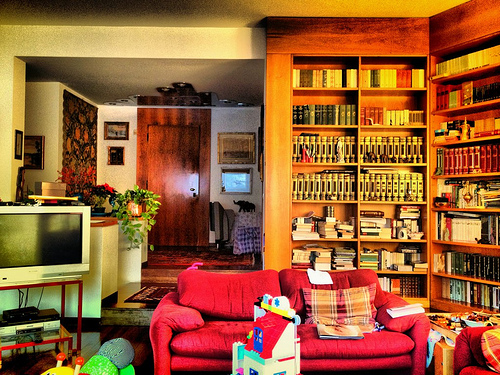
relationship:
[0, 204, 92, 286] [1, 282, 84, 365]
television on stand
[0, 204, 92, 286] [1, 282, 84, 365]
television on top of stand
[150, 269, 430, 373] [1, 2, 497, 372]
sofa in home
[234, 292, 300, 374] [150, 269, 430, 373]
toy in front of sofa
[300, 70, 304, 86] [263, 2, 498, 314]
book inside bookcase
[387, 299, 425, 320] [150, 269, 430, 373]
book on top of sofa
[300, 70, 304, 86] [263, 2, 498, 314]
book on bookcase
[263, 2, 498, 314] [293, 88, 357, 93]
bookcase has shelf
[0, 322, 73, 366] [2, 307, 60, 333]
table has electronics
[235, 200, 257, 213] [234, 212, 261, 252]
elephant on top of tablecloth